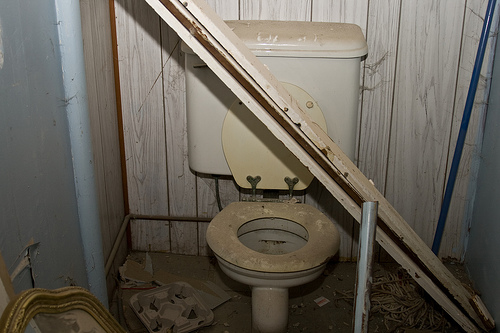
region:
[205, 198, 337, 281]
Dirty white and brown toilet seat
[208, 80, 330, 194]
Yellowish porcelain toilet seat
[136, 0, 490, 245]
White wood panel wall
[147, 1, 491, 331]
large fall white wood plank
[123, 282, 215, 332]
Brownish card board cup holder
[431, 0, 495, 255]
Sold blue pole on the wall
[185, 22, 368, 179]
White porcelain toilet tank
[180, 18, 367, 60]
Dusty white tank top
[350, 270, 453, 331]
Super dirty mop head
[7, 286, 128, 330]
Fallen gold picture frame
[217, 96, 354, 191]
Toilet has white lid.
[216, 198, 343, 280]
Toilet has white seat.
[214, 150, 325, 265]
Toilet lid is up.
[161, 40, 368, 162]
Tank on toilet is white.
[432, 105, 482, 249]
Blue handle on mop.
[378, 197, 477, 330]
Mop is in corner of room.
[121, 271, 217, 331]
Togo cup holder on floor.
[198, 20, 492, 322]
Pieces of wood leaning over toilet.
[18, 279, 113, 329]
Off white fame leaning against wall.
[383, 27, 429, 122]
Wood paneling on back wall.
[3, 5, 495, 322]
a very old looking bathroom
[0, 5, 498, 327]
the bathroom looks very dirty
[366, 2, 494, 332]
a mop in the bathroom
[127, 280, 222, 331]
cup holder on the bathroom floor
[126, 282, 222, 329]
the cup holder is tan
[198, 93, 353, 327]
the toilet in the bathroom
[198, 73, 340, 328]
the toilet is white and tan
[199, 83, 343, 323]
the toilet has dirt on it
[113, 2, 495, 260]
a wooden wall behind the toilet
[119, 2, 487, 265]
the wooden wall is tan and brow in color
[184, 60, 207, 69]
flash handle of a toilet bowl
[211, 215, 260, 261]
a toilet seat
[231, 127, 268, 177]
an opened toilet cover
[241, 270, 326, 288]
a toilet bowl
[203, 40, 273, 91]
a wooden timber in the toilet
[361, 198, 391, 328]
a metal bar in the toilet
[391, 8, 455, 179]
a wooden wall in the toilet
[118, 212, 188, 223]
a water pipe to the toilet bowl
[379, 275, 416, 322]
the woolen part of a mob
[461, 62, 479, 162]
the handle of a mob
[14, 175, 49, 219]
this is the wall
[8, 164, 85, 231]
the wall is white in color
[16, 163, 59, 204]
the wall is clean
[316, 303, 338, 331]
this is the ground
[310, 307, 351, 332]
the ground is dirty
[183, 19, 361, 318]
this is a toilet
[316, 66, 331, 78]
the toilet is white in color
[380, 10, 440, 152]
this is a door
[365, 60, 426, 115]
the door is wooden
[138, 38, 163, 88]
the door is brown in color